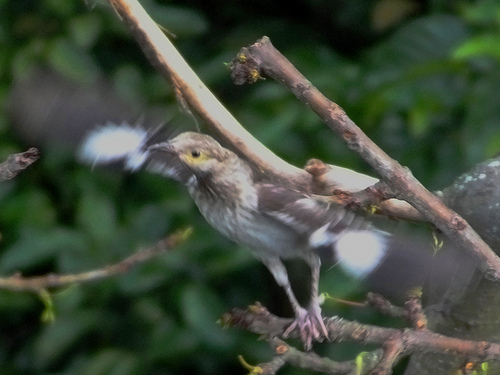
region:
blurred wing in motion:
[20, 76, 155, 175]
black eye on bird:
[188, 143, 212, 162]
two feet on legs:
[283, 305, 328, 347]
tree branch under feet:
[245, 297, 435, 342]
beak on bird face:
[146, 137, 178, 157]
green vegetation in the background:
[365, 38, 477, 136]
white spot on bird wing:
[330, 228, 390, 273]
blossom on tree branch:
[36, 283, 59, 330]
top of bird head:
[180, 129, 215, 147]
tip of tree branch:
[238, 26, 273, 82]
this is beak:
[146, 138, 176, 154]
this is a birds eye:
[184, 145, 219, 165]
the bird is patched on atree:
[151, 130, 348, 348]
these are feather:
[225, 182, 295, 224]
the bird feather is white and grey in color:
[228, 183, 298, 218]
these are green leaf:
[37, 191, 124, 252]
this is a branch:
[222, 12, 406, 146]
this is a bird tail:
[329, 195, 392, 245]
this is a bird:
[142, 120, 363, 315]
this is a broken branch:
[220, 29, 291, 87]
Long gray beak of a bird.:
[146, 140, 177, 155]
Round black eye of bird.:
[190, 151, 201, 159]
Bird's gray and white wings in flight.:
[16, 82, 193, 190]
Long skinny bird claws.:
[281, 282, 329, 351]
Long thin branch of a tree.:
[223, 34, 497, 282]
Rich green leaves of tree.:
[342, 14, 499, 112]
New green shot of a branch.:
[36, 287, 57, 324]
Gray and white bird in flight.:
[8, 71, 473, 354]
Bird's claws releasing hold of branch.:
[219, 298, 394, 351]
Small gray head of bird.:
[144, 129, 230, 177]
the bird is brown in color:
[145, 126, 309, 298]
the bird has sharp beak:
[153, 140, 169, 153]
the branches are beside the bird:
[387, 185, 494, 372]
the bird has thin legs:
[286, 264, 326, 339]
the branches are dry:
[406, 186, 496, 366]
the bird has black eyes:
[189, 149, 205, 161]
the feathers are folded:
[231, 187, 326, 224]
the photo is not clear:
[8, 2, 499, 372]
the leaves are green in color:
[48, 194, 134, 240]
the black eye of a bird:
[189, 145, 201, 158]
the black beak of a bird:
[146, 137, 178, 155]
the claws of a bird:
[277, 264, 332, 350]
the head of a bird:
[143, 127, 233, 184]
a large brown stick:
[224, 34, 499, 283]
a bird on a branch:
[146, 130, 395, 353]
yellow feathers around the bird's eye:
[182, 147, 210, 164]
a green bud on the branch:
[349, 348, 375, 373]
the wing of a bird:
[241, 161, 483, 306]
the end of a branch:
[223, 32, 275, 89]